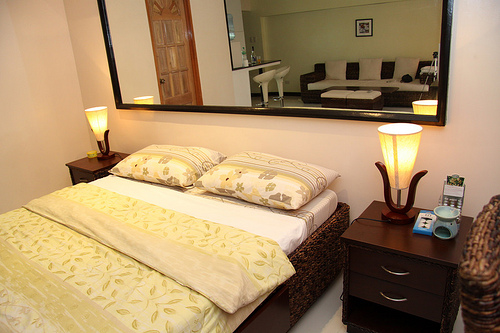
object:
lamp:
[377, 123, 423, 190]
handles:
[381, 265, 410, 276]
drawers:
[340, 199, 474, 333]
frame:
[96, 0, 454, 127]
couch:
[299, 58, 440, 108]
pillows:
[192, 150, 341, 210]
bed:
[0, 145, 349, 333]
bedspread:
[70, 170, 338, 257]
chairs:
[252, 69, 275, 107]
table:
[339, 200, 476, 265]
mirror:
[101, 0, 445, 117]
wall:
[450, 13, 494, 134]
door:
[144, 0, 203, 106]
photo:
[354, 18, 372, 38]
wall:
[275, 21, 449, 67]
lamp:
[84, 106, 107, 142]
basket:
[420, 63, 437, 86]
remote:
[413, 210, 439, 236]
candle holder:
[432, 206, 462, 240]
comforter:
[0, 181, 296, 332]